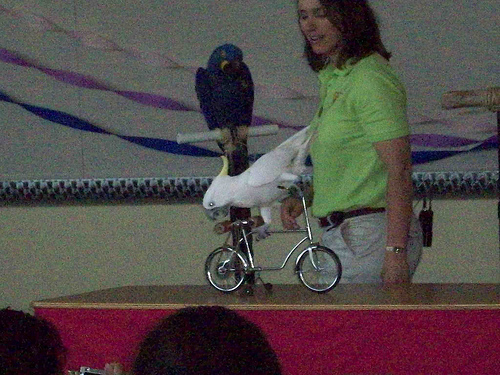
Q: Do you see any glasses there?
A: No, there are no glasses.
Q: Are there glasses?
A: No, there are no glasses.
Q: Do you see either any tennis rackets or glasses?
A: No, there are no glasses or tennis rackets.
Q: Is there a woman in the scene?
A: Yes, there is a woman.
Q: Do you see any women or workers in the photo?
A: Yes, there is a woman.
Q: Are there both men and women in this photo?
A: No, there is a woman but no men.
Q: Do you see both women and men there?
A: No, there is a woman but no men.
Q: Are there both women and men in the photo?
A: No, there is a woman but no men.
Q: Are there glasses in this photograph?
A: No, there are no glasses.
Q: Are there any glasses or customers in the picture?
A: No, there are no glasses or customers.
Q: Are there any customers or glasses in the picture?
A: No, there are no glasses or customers.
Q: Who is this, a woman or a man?
A: This is a woman.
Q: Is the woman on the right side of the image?
A: Yes, the woman is on the right of the image.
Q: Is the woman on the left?
A: No, the woman is on the right of the image.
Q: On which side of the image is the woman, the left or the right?
A: The woman is on the right of the image.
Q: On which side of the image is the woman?
A: The woman is on the right of the image.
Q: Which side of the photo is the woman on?
A: The woman is on the right of the image.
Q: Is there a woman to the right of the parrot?
A: Yes, there is a woman to the right of the parrot.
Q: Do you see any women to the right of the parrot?
A: Yes, there is a woman to the right of the parrot.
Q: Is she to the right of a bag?
A: No, the woman is to the right of the parrot.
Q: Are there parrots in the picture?
A: Yes, there is a parrot.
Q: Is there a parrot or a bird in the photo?
A: Yes, there is a parrot.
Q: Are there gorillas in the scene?
A: No, there are no gorillas.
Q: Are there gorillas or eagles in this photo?
A: No, there are no gorillas or eagles.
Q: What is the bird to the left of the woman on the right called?
A: The bird is a parrot.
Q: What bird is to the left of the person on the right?
A: The bird is a parrot.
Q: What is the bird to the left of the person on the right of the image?
A: The bird is a parrot.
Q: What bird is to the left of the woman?
A: The bird is a parrot.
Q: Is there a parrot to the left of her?
A: Yes, there is a parrot to the left of the woman.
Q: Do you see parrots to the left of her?
A: Yes, there is a parrot to the left of the woman.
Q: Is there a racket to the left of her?
A: No, there is a parrot to the left of the woman.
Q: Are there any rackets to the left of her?
A: No, there is a parrot to the left of the woman.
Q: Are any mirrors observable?
A: No, there are no mirrors.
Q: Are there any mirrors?
A: No, there are no mirrors.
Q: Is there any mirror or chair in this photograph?
A: No, there are no mirrors or chairs.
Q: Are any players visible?
A: No, there are no players.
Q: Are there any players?
A: No, there are no players.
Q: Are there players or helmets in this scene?
A: No, there are no players or helmets.